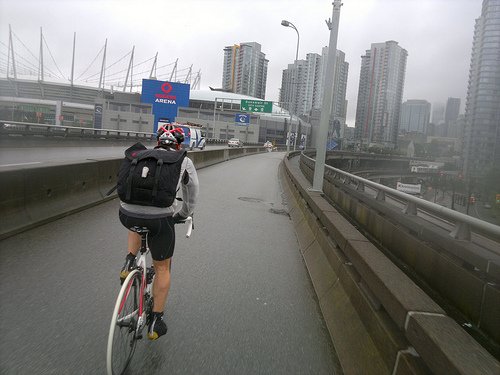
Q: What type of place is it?
A: It is a path.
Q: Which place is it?
A: It is a path.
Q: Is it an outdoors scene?
A: Yes, it is outdoors.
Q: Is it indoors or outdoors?
A: It is outdoors.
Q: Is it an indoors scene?
A: No, it is outdoors.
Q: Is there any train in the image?
A: No, there are no trains.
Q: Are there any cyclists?
A: Yes, there is a cyclist.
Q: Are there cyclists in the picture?
A: Yes, there is a cyclist.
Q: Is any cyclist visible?
A: Yes, there is a cyclist.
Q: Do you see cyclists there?
A: Yes, there is a cyclist.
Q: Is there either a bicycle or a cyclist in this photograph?
A: Yes, there is a cyclist.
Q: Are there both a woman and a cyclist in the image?
A: No, there is a cyclist but no women.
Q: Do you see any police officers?
A: No, there are no police officers.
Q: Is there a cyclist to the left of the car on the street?
A: Yes, there is a cyclist to the left of the car.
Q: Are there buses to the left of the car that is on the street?
A: No, there is a cyclist to the left of the car.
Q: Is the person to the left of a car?
A: Yes, the cyclist is to the left of a car.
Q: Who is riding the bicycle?
A: The bicyclist is riding the bicycle.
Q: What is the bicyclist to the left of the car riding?
A: The bicyclist is riding the bicycle.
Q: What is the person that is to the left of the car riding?
A: The bicyclist is riding the bicycle.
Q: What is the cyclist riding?
A: The bicyclist is riding the bicycle.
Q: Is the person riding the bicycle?
A: Yes, the cyclist is riding the bicycle.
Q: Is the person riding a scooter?
A: No, the cyclist is riding the bicycle.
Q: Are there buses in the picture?
A: No, there are no buses.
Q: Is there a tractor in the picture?
A: No, there are no tractors.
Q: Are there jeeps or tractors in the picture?
A: No, there are no tractors or jeeps.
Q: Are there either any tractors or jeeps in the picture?
A: No, there are no tractors or jeeps.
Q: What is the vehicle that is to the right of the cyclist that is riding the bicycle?
A: The vehicle is a car.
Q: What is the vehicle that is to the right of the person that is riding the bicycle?
A: The vehicle is a car.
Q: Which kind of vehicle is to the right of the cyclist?
A: The vehicle is a car.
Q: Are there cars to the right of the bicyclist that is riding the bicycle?
A: Yes, there is a car to the right of the cyclist.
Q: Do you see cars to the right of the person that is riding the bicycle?
A: Yes, there is a car to the right of the cyclist.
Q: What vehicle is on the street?
A: The vehicle is a car.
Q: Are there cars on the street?
A: Yes, there is a car on the street.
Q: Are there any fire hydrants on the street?
A: No, there is a car on the street.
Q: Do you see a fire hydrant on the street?
A: No, there is a car on the street.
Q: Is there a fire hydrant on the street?
A: No, there is a car on the street.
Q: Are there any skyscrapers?
A: Yes, there is a skyscraper.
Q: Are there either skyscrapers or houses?
A: Yes, there is a skyscraper.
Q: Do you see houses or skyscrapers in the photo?
A: Yes, there is a skyscraper.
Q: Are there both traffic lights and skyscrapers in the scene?
A: No, there is a skyscraper but no traffic lights.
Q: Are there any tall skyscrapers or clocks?
A: Yes, there is a tall skyscraper.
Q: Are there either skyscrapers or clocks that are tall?
A: Yes, the skyscraper is tall.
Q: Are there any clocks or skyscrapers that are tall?
A: Yes, the skyscraper is tall.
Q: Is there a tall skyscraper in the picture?
A: Yes, there is a tall skyscraper.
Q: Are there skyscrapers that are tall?
A: Yes, there is a skyscraper that is tall.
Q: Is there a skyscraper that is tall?
A: Yes, there is a skyscraper that is tall.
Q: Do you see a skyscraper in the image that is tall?
A: Yes, there is a skyscraper that is tall.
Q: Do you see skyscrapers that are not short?
A: Yes, there is a tall skyscraper.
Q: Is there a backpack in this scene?
A: Yes, there is a backpack.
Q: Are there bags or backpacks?
A: Yes, there is a backpack.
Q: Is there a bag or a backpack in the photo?
A: Yes, there is a backpack.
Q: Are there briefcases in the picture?
A: No, there are no briefcases.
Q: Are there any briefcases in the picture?
A: No, there are no briefcases.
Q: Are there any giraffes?
A: No, there are no giraffes.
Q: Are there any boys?
A: No, there are no boys.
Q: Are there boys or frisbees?
A: No, there are no boys or frisbees.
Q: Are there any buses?
A: No, there are no buses.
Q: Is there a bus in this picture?
A: No, there are no buses.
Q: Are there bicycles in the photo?
A: Yes, there is a bicycle.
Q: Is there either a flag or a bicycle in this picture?
A: Yes, there is a bicycle.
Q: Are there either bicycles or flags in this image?
A: Yes, there is a bicycle.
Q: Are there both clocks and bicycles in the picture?
A: No, there is a bicycle but no clocks.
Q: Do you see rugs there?
A: No, there are no rugs.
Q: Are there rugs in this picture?
A: No, there are no rugs.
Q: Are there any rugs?
A: No, there are no rugs.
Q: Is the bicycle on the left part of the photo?
A: Yes, the bicycle is on the left of the image.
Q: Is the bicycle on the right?
A: No, the bicycle is on the left of the image.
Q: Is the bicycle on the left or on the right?
A: The bicycle is on the left of the image.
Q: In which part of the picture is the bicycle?
A: The bicycle is on the left of the image.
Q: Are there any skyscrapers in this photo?
A: Yes, there is a skyscraper.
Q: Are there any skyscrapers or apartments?
A: Yes, there is a skyscraper.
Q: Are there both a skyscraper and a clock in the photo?
A: No, there is a skyscraper but no clocks.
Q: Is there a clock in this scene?
A: No, there are no clocks.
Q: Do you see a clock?
A: No, there are no clocks.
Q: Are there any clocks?
A: No, there are no clocks.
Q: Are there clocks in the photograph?
A: No, there are no clocks.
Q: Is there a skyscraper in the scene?
A: Yes, there is a skyscraper.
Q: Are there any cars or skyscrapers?
A: Yes, there is a skyscraper.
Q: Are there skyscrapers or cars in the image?
A: Yes, there is a skyscraper.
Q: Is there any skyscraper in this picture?
A: Yes, there is a skyscraper.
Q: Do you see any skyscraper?
A: Yes, there is a skyscraper.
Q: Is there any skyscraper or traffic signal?
A: Yes, there is a skyscraper.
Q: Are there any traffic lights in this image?
A: No, there are no traffic lights.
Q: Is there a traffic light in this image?
A: No, there are no traffic lights.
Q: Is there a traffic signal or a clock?
A: No, there are no traffic lights or clocks.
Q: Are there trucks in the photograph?
A: No, there are no trucks.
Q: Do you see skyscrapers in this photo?
A: Yes, there is a skyscraper.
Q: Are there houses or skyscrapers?
A: Yes, there is a skyscraper.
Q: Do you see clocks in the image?
A: No, there are no clocks.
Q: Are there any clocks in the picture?
A: No, there are no clocks.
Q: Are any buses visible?
A: No, there are no buses.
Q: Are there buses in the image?
A: No, there are no buses.